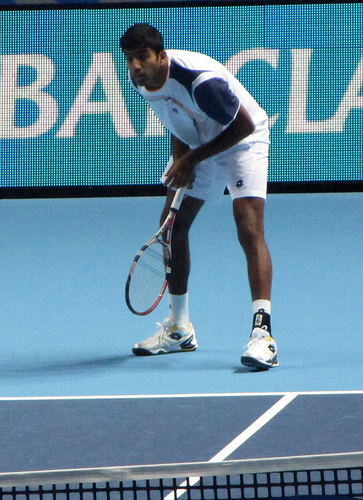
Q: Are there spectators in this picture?
A: No, there are no spectators.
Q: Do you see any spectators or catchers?
A: No, there are no spectators or catchers.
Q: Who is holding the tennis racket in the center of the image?
A: The man is holding the racket.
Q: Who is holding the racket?
A: The man is holding the racket.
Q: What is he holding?
A: The man is holding the racket.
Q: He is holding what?
A: The man is holding the racket.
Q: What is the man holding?
A: The man is holding the racket.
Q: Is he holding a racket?
A: Yes, the man is holding a racket.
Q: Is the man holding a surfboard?
A: No, the man is holding a racket.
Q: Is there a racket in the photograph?
A: Yes, there is a racket.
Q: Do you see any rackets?
A: Yes, there is a racket.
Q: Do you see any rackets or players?
A: Yes, there is a racket.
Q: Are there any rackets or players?
A: Yes, there is a racket.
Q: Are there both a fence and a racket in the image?
A: No, there is a racket but no fences.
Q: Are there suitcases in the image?
A: No, there are no suitcases.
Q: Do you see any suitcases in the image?
A: No, there are no suitcases.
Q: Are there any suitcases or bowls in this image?
A: No, there are no suitcases or bowls.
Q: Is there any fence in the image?
A: No, there are no fences.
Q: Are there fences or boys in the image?
A: No, there are no fences or boys.